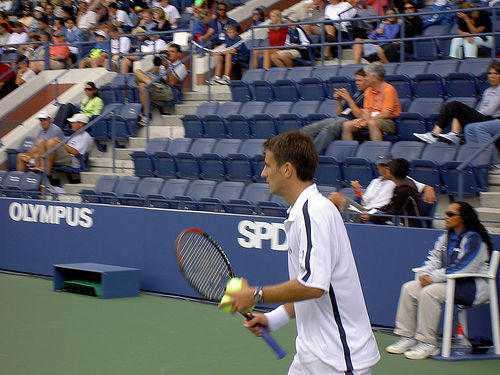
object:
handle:
[261, 327, 289, 360]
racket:
[171, 226, 289, 365]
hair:
[267, 133, 318, 181]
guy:
[225, 130, 383, 375]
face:
[258, 147, 287, 196]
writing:
[5, 201, 97, 228]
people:
[363, 158, 422, 227]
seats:
[440, 142, 497, 200]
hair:
[460, 203, 492, 254]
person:
[385, 202, 500, 362]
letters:
[237, 219, 292, 251]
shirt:
[362, 84, 400, 117]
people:
[343, 63, 399, 143]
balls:
[225, 278, 246, 297]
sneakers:
[404, 342, 441, 360]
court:
[0, 267, 499, 375]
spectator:
[340, 66, 404, 144]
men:
[16, 111, 65, 170]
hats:
[67, 113, 90, 124]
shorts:
[53, 149, 73, 167]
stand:
[51, 257, 142, 299]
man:
[132, 43, 188, 125]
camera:
[152, 49, 169, 66]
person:
[412, 60, 499, 144]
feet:
[412, 129, 442, 144]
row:
[131, 133, 488, 169]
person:
[59, 80, 105, 126]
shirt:
[362, 175, 425, 215]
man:
[325, 158, 436, 214]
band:
[264, 303, 293, 334]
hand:
[216, 279, 260, 314]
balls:
[220, 295, 238, 315]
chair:
[413, 249, 500, 362]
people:
[0, 15, 28, 41]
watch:
[253, 287, 265, 305]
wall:
[0, 197, 500, 351]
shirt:
[279, 187, 379, 371]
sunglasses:
[446, 210, 463, 217]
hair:
[364, 62, 385, 79]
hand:
[243, 310, 269, 344]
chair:
[138, 69, 183, 104]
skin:
[271, 284, 304, 300]